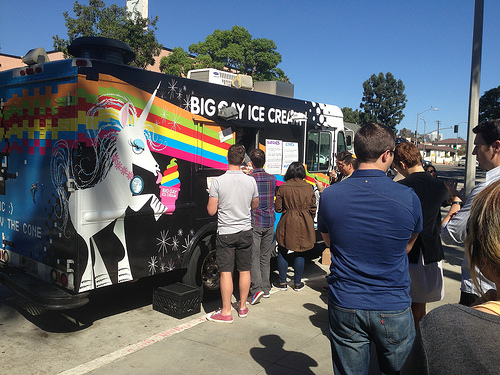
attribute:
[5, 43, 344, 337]
truck — black, large, colorful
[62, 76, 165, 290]
unicorn — white, creative, pretty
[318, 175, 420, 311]
shirt — blue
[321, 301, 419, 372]
jeans — blue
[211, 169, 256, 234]
shirt — gray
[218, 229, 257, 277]
shorts — black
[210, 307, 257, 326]
shoes — red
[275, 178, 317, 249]
coat — brown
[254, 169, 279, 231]
shirt — blue, plaid, red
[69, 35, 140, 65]
vent — black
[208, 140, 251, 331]
person — standing, deciding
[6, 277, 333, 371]
pavement — small, gray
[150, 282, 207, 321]
crate — small, black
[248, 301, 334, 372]
shadow — black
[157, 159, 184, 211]
ice cream cone — colorful, rainbow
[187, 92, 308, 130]
letters — white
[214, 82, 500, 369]
people — standing, watching, ordering, eating, waiting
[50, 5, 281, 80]
trees — large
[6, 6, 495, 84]
sky — clear, blue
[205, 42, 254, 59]
leaves — green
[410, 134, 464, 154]
roofs — brown